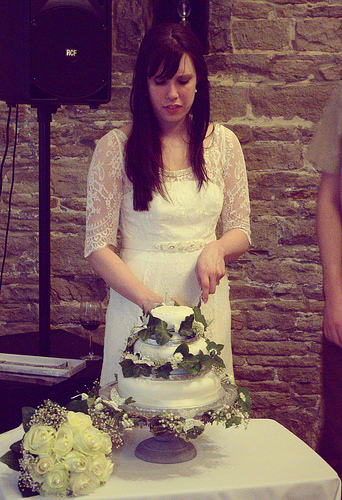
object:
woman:
[83, 16, 252, 391]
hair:
[122, 20, 215, 214]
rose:
[73, 424, 103, 457]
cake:
[115, 296, 224, 410]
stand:
[97, 383, 252, 465]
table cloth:
[0, 418, 341, 499]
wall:
[0, 0, 341, 456]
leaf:
[0, 449, 23, 472]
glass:
[78, 296, 102, 363]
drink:
[79, 321, 101, 331]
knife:
[191, 287, 203, 308]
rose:
[22, 422, 58, 457]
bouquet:
[0, 398, 125, 498]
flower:
[156, 410, 185, 435]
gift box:
[0, 352, 86, 387]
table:
[0, 329, 104, 434]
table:
[0, 417, 342, 499]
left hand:
[194, 240, 227, 304]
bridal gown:
[82, 120, 252, 386]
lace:
[82, 121, 252, 258]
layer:
[147, 305, 195, 337]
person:
[304, 78, 342, 475]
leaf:
[177, 313, 197, 338]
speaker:
[0, 0, 113, 359]